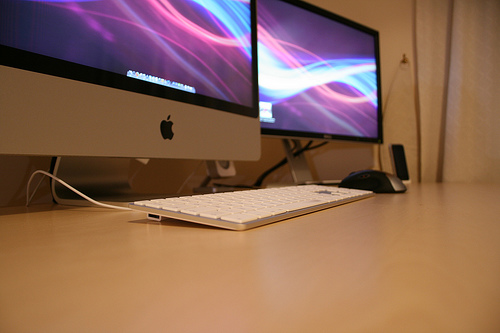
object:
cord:
[24, 169, 134, 211]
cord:
[174, 159, 203, 194]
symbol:
[159, 113, 174, 141]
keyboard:
[129, 184, 374, 231]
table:
[0, 183, 499, 332]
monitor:
[0, 0, 262, 161]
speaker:
[388, 143, 412, 184]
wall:
[371, 0, 419, 182]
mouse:
[338, 168, 406, 192]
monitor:
[255, 0, 383, 143]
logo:
[159, 113, 175, 140]